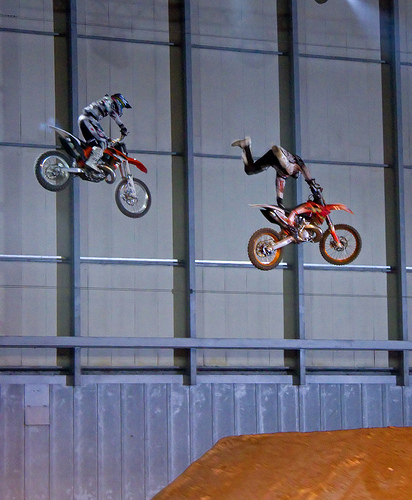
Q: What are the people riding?
A: Dirt bikes.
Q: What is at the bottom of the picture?
A: Ramp.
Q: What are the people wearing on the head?
A: Helmets.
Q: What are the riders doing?
A: Stunts.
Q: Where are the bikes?
A: In the air.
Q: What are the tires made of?
A: Rubber.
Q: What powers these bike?
A: Motor/engine.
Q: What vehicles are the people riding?
A: Dirt bikes.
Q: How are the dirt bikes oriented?
A: In the air.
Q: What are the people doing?
A: Tricks.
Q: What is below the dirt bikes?
A: A ramp.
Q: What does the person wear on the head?
A: A helmet.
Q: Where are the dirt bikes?
A: In a large structure.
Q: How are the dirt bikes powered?
A: Engines.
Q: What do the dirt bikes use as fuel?
A: Gasoline.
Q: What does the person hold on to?
A: The handlebars.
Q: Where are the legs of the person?
A: In the air.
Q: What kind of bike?
A: Dirt.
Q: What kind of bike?
A: Dirt.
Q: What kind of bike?
A: Dirt.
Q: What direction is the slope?
A: Upward.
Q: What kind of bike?
A: Dirt.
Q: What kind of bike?
A: Dirt.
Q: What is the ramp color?
A: Brown.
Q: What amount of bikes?
A: Two.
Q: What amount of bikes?
A: Two.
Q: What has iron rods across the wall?
A: The building.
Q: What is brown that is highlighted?
A: The front portion of a sand mound.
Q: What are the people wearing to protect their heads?
A: Helmets.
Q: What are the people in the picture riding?
A: Motorcycles.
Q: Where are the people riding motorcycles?
A: At a stunt arena.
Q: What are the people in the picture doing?
A: Motorcycle tricks.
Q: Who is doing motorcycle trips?
A: Two people.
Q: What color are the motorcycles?
A: Black and red.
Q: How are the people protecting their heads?
A: They're wearing helmets.